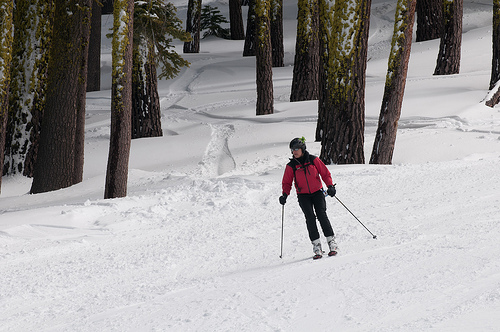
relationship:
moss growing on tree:
[111, 1, 128, 101] [105, 1, 132, 196]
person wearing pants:
[280, 137, 339, 257] [296, 190, 335, 240]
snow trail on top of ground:
[80, 0, 500, 181] [1, 1, 498, 331]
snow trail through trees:
[80, 0, 500, 181] [0, 1, 498, 198]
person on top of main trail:
[280, 137, 339, 257] [2, 164, 499, 330]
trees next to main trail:
[0, 1, 498, 198] [2, 164, 499, 330]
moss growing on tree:
[327, 1, 357, 102] [319, 0, 368, 161]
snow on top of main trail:
[0, 2, 497, 328] [2, 164, 499, 330]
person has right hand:
[280, 137, 339, 257] [280, 194, 287, 205]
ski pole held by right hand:
[278, 202, 285, 255] [280, 194, 287, 205]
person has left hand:
[280, 137, 339, 257] [327, 185, 336, 196]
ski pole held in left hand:
[333, 194, 377, 241] [327, 185, 336, 196]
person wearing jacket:
[280, 137, 339, 257] [282, 155, 333, 194]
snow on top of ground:
[0, 2, 497, 328] [1, 1, 498, 331]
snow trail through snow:
[80, 0, 500, 181] [0, 2, 497, 328]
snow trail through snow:
[164, 62, 498, 139] [0, 2, 497, 328]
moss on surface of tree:
[256, 0, 272, 44] [253, 0, 274, 115]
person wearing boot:
[280, 137, 339, 257] [325, 236, 340, 255]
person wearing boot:
[280, 137, 339, 257] [311, 240, 324, 259]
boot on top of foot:
[325, 236, 340, 255] [329, 246, 340, 255]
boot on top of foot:
[311, 240, 324, 259] [313, 252, 324, 259]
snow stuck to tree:
[118, 9, 126, 49] [105, 1, 132, 196]